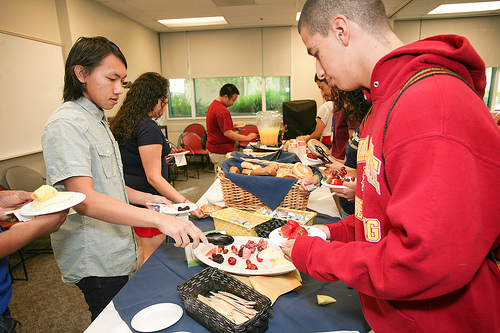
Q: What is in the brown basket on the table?
A: Bread.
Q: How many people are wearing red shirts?
A: 2.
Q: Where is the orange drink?
A: At the end of the table.